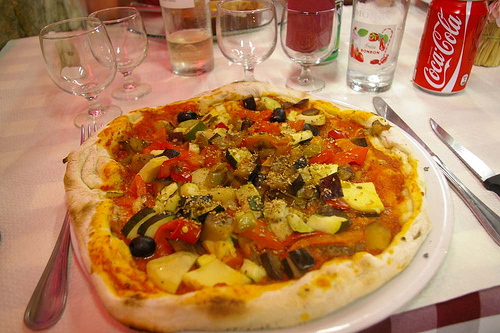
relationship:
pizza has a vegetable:
[63, 80, 430, 330] [180, 194, 225, 221]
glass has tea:
[158, 1, 215, 77] [166, 28, 216, 76]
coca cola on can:
[421, 7, 461, 91] [412, 0, 489, 96]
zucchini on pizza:
[122, 207, 166, 242] [63, 80, 430, 330]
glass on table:
[38, 18, 118, 126] [2, 1, 497, 332]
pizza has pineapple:
[63, 80, 430, 330] [342, 180, 382, 215]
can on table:
[412, 0, 489, 96] [2, 1, 497, 332]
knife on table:
[431, 115, 500, 196] [2, 1, 497, 332]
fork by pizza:
[24, 122, 112, 329] [63, 80, 430, 330]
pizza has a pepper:
[63, 80, 430, 330] [175, 219, 201, 244]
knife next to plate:
[372, 94, 499, 255] [65, 86, 454, 332]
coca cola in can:
[421, 7, 461, 91] [412, 0, 489, 96]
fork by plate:
[24, 122, 112, 329] [65, 86, 454, 332]